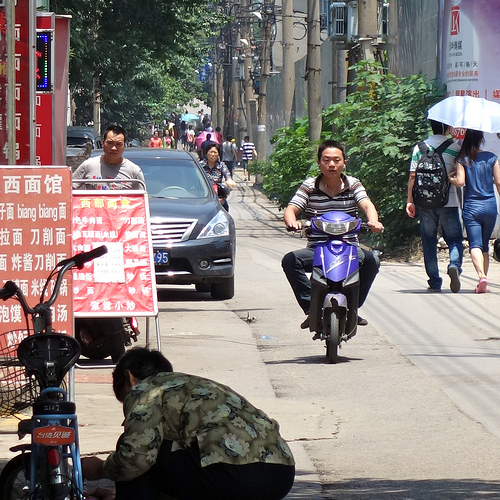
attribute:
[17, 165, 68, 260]
sign — red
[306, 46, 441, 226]
plant — large, green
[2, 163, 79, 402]
sign — red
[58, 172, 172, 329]
sign — red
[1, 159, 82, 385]
sign — red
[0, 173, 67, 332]
symbols — white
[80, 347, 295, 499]
man — leaning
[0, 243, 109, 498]
bike — blue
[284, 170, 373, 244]
shirt — short sleeved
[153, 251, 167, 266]
license plate — blue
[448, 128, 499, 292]
person — walking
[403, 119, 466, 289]
person — walking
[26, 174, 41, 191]
sign — red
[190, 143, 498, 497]
road — asphalt, grey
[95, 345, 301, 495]
woman — crouching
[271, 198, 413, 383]
moped — blue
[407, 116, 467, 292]
man — young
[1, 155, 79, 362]
sign — red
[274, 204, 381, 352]
scooter — blue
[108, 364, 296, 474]
shirt — floral-patterned